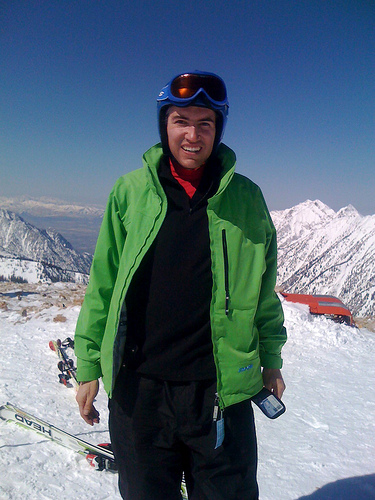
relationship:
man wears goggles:
[73, 67, 286, 500] [155, 71, 226, 166]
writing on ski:
[13, 412, 55, 441] [5, 398, 122, 482]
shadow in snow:
[297, 473, 374, 497] [0, 196, 375, 500]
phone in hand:
[251, 384, 286, 424] [259, 362, 285, 401]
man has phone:
[73, 67, 286, 500] [251, 384, 286, 424]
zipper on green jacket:
[99, 194, 231, 423] [75, 140, 285, 410]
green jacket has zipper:
[75, 140, 285, 410] [222, 223, 235, 316]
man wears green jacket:
[73, 67, 286, 500] [75, 140, 285, 418]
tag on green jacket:
[211, 402, 225, 447] [75, 140, 285, 410]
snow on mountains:
[0, 196, 375, 500] [268, 199, 373, 312]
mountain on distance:
[1, 192, 91, 293] [3, 203, 106, 240]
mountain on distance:
[267, 202, 373, 298] [5, 194, 373, 263]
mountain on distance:
[3, 203, 91, 292] [5, 194, 373, 263]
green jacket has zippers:
[75, 140, 285, 410] [217, 223, 236, 323]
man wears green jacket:
[73, 67, 286, 500] [75, 140, 285, 410]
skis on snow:
[1, 0, 113, 79] [7, 331, 91, 483]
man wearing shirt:
[73, 67, 286, 500] [172, 158, 208, 196]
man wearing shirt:
[73, 67, 286, 500] [122, 157, 221, 382]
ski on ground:
[1, 395, 117, 478] [0, 275, 373, 496]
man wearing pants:
[73, 67, 286, 500] [108, 361, 268, 498]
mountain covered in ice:
[267, 202, 373, 298] [296, 206, 340, 264]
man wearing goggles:
[67, 67, 298, 500] [156, 63, 236, 108]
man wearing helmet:
[73, 67, 286, 500] [153, 68, 231, 153]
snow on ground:
[0, 196, 375, 500] [0, 275, 373, 496]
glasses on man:
[157, 71, 229, 108] [73, 67, 286, 500]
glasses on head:
[157, 71, 229, 108] [157, 70, 229, 164]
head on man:
[157, 70, 229, 164] [73, 67, 286, 500]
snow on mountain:
[4, 196, 372, 499] [264, 198, 373, 331]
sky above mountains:
[4, 2, 371, 200] [272, 201, 374, 302]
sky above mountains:
[4, 2, 371, 200] [1, 198, 88, 284]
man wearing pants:
[73, 67, 286, 500] [84, 384, 303, 474]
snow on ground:
[4, 196, 372, 499] [288, 304, 373, 492]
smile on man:
[180, 142, 204, 154] [73, 67, 286, 500]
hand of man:
[259, 365, 286, 400] [73, 67, 286, 500]